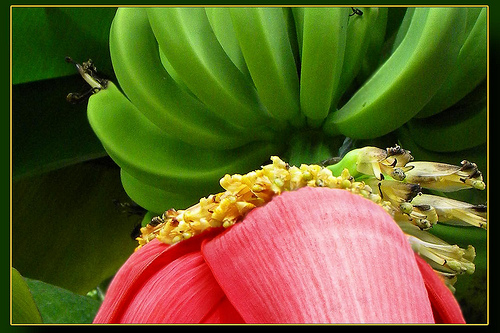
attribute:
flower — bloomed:
[62, 7, 490, 329]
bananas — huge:
[60, 8, 482, 277]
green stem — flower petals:
[113, 28, 458, 199]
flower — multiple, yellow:
[364, 154, 466, 254]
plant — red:
[95, 190, 462, 325]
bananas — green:
[83, 12, 496, 240]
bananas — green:
[326, 141, 481, 273]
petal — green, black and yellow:
[311, 125, 489, 285]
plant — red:
[66, 141, 485, 322]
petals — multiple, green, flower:
[138, 32, 444, 183]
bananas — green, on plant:
[68, 5, 487, 229]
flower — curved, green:
[90, 145, 488, 324]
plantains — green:
[68, 11, 460, 303]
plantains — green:
[33, 24, 361, 236]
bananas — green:
[69, 9, 479, 209]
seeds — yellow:
[149, 149, 393, 239]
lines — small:
[288, 247, 377, 322]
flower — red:
[128, 142, 413, 271]